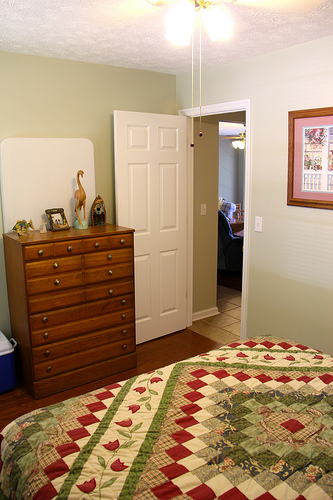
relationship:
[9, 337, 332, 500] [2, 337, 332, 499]
quilt on bed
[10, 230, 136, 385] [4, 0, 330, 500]
chest of drawers in room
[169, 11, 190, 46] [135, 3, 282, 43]
lamps on ceiling fan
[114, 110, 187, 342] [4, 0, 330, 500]
door open to room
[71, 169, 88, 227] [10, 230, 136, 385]
dinosaur models on top of dresser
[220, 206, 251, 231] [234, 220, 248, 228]
man holding book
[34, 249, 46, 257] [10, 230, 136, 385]
brass knobs on dresser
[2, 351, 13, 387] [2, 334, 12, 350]
blue cooler with a white lid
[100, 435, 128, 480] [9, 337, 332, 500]
red flowers on quilt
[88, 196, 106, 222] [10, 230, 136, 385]
fish figurine on top of chest of drawers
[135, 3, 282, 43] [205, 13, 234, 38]
ceiling fan with light fixtures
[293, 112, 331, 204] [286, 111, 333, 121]
picture on wall has wooden frame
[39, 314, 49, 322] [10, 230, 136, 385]
brass handle on dresser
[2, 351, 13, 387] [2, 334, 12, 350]
blue plastic box with a white lid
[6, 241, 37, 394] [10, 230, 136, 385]
golden frame on dresser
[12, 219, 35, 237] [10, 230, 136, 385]
decorative bird on top of dresser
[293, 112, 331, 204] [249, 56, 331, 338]
wood frame on white wall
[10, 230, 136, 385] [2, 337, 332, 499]
dresser next to bed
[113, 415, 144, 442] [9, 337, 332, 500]
flower prints on quilt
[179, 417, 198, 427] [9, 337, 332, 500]
red patch on quilt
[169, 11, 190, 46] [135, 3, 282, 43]
light and ceiling fan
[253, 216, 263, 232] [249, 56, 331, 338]
light switch on wall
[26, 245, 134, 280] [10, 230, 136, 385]
drawer on dresser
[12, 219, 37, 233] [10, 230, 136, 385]
decorative bird sitting on top of dresser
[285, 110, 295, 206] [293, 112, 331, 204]
wooden picture frame holding picture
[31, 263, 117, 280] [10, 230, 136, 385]
drawer on dresser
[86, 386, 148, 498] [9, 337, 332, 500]
flower prints on top of quilt